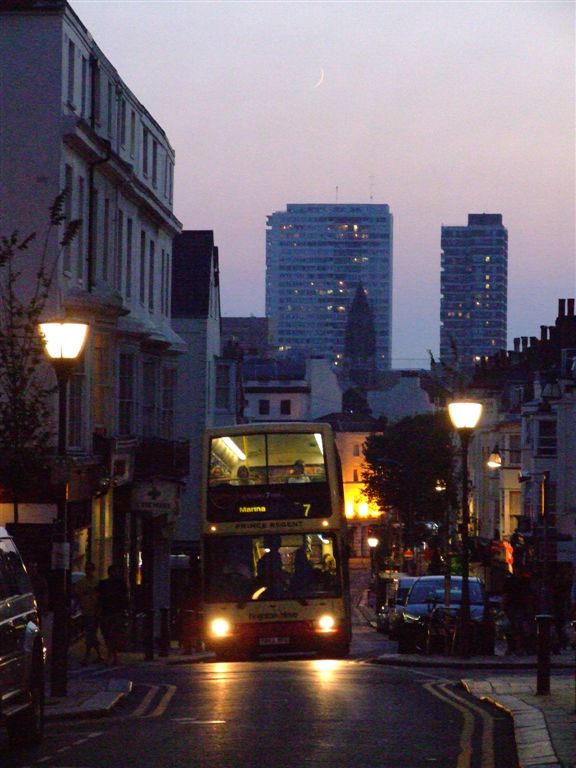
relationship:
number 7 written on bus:
[300, 500, 314, 519] [195, 417, 356, 664]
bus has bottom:
[195, 417, 356, 664] [200, 525, 353, 658]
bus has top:
[195, 417, 356, 664] [201, 420, 346, 533]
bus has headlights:
[195, 417, 356, 664] [204, 613, 340, 640]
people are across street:
[75, 561, 128, 667] [110, 656, 513, 767]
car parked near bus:
[398, 575, 498, 656] [195, 417, 356, 664]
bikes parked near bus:
[418, 593, 482, 660] [195, 417, 356, 664]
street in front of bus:
[110, 656, 513, 767] [195, 417, 356, 664]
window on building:
[115, 348, 138, 446] [2, 4, 177, 654]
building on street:
[2, 4, 177, 654] [110, 656, 513, 767]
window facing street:
[115, 348, 138, 446] [110, 656, 513, 767]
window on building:
[66, 322, 88, 454] [2, 4, 177, 654]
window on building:
[90, 332, 117, 438] [2, 4, 177, 654]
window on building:
[137, 353, 159, 443] [2, 4, 177, 654]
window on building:
[157, 361, 181, 453] [2, 4, 177, 654]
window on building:
[61, 158, 76, 286] [2, 4, 177, 654]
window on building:
[74, 169, 87, 289] [2, 4, 177, 654]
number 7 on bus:
[300, 500, 314, 519] [195, 417, 356, 664]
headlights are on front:
[204, 613, 340, 640] [203, 599, 354, 660]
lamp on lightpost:
[444, 398, 487, 433] [456, 426, 473, 662]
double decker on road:
[195, 417, 356, 664] [110, 656, 513, 767]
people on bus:
[233, 457, 313, 486] [195, 417, 356, 664]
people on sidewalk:
[75, 561, 128, 667] [36, 631, 205, 716]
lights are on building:
[338, 484, 387, 524] [317, 391, 401, 561]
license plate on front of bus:
[257, 634, 297, 649] [195, 417, 356, 664]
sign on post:
[123, 475, 180, 518] [143, 511, 156, 663]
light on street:
[35, 321, 91, 360] [110, 656, 513, 767]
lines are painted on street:
[420, 667, 498, 767] [110, 656, 513, 767]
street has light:
[110, 656, 513, 767] [35, 321, 91, 360]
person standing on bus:
[256, 537, 285, 594] [195, 417, 356, 664]